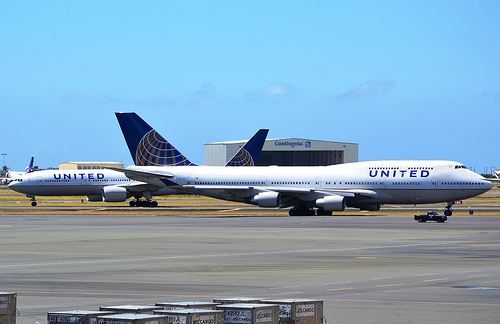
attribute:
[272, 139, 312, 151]
logo — large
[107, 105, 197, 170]
tail fin — gold, blue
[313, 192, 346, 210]
engine — white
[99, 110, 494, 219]
plane — large, blue, white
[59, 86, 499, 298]
windows — upper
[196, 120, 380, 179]
hanger — white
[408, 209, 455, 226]
truck — small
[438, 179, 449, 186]
window — small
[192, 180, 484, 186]
windows — small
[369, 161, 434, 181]
letters — blue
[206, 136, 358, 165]
hangar — white